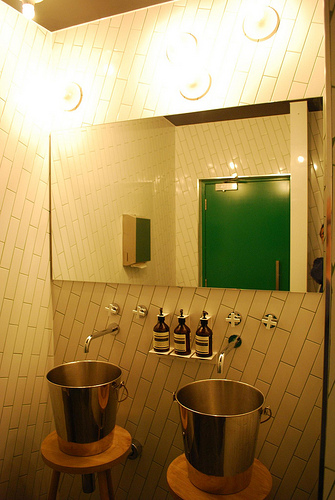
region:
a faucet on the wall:
[215, 328, 246, 371]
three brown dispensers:
[146, 305, 214, 357]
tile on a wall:
[277, 341, 314, 400]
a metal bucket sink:
[166, 375, 276, 490]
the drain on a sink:
[79, 470, 96, 490]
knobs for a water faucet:
[223, 308, 279, 330]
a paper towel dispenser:
[118, 207, 157, 271]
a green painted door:
[213, 196, 288, 291]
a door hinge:
[202, 196, 209, 211]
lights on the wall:
[161, 27, 215, 95]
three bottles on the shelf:
[132, 304, 222, 359]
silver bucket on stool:
[174, 375, 259, 495]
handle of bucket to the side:
[115, 375, 128, 405]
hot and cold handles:
[223, 310, 300, 341]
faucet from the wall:
[211, 344, 249, 373]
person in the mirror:
[313, 198, 329, 291]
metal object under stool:
[73, 470, 96, 494]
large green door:
[184, 173, 295, 289]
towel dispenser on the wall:
[118, 208, 148, 283]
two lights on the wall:
[49, 82, 218, 107]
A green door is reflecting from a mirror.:
[191, 176, 333, 295]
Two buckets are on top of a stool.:
[47, 365, 285, 493]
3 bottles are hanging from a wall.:
[151, 310, 219, 359]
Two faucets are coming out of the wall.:
[81, 321, 248, 377]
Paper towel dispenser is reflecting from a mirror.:
[115, 211, 163, 271]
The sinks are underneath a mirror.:
[41, 294, 261, 459]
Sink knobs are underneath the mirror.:
[69, 297, 302, 347]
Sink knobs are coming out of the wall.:
[100, 305, 299, 332]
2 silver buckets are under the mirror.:
[23, 363, 261, 463]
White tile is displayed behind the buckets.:
[54, 297, 288, 498]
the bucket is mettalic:
[168, 384, 271, 495]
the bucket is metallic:
[49, 355, 124, 455]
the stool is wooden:
[166, 456, 278, 499]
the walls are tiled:
[266, 337, 325, 396]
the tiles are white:
[265, 348, 313, 384]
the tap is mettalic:
[212, 343, 236, 373]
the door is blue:
[205, 191, 282, 277]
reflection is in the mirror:
[128, 147, 318, 293]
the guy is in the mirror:
[315, 226, 333, 290]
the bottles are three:
[149, 319, 218, 356]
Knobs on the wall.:
[94, 288, 290, 337]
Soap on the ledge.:
[142, 291, 239, 396]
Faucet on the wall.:
[78, 311, 133, 362]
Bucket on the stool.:
[32, 347, 145, 451]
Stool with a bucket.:
[38, 425, 153, 492]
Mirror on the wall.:
[38, 110, 334, 289]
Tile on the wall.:
[37, 296, 75, 338]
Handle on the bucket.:
[250, 394, 297, 440]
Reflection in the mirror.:
[106, 179, 296, 279]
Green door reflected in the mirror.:
[190, 162, 307, 296]